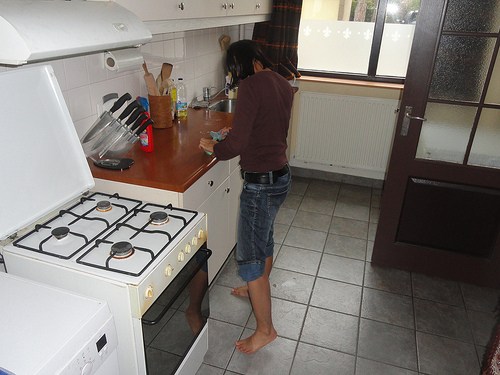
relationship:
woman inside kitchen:
[198, 38, 296, 354] [1, 0, 499, 374]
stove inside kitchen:
[2, 191, 203, 288] [1, 0, 499, 374]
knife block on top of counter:
[76, 109, 139, 166] [85, 87, 234, 192]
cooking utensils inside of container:
[140, 59, 176, 95] [147, 93, 174, 130]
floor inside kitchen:
[192, 174, 499, 374] [1, 0, 499, 374]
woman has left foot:
[198, 38, 296, 354] [234, 327, 278, 356]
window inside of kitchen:
[296, 1, 421, 79] [1, 0, 499, 374]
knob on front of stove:
[143, 281, 154, 300] [2, 191, 203, 288]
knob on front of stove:
[164, 263, 175, 278] [2, 191, 203, 288]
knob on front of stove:
[176, 249, 186, 260] [2, 191, 203, 288]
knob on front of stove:
[183, 241, 191, 255] [2, 191, 203, 288]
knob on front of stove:
[189, 235, 200, 247] [2, 191, 203, 288]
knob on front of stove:
[196, 227, 207, 240] [2, 191, 203, 288]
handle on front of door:
[397, 104, 427, 138] [370, 1, 498, 291]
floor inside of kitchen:
[192, 174, 499, 374] [1, 0, 499, 374]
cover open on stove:
[0, 63, 94, 240] [2, 191, 203, 288]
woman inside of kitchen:
[198, 38, 296, 354] [1, 0, 499, 374]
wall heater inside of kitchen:
[294, 90, 400, 174] [1, 0, 499, 374]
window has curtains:
[296, 1, 421, 79] [249, 0, 305, 94]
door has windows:
[370, 1, 498, 291] [414, 1, 499, 174]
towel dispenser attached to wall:
[103, 48, 144, 71] [0, 20, 241, 142]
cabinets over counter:
[112, 0, 270, 36] [85, 87, 234, 192]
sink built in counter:
[207, 96, 237, 115] [85, 87, 234, 192]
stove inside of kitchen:
[2, 191, 203, 288] [1, 0, 499, 374]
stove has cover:
[2, 191, 203, 288] [0, 63, 94, 240]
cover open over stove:
[0, 63, 94, 240] [2, 191, 203, 288]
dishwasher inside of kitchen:
[48, 314, 123, 374] [1, 0, 499, 374]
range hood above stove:
[0, 0, 152, 69] [2, 191, 203, 288]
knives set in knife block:
[83, 93, 152, 159] [76, 109, 139, 166]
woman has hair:
[198, 38, 296, 354] [224, 37, 275, 86]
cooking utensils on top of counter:
[142, 62, 176, 96] [85, 87, 234, 192]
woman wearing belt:
[198, 38, 296, 354] [237, 163, 288, 183]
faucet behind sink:
[205, 83, 232, 103] [207, 96, 237, 115]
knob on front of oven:
[192, 237, 199, 246] [4, 189, 209, 374]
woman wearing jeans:
[198, 38, 296, 354] [234, 169, 290, 283]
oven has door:
[4, 189, 209, 374] [142, 239, 210, 374]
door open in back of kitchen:
[370, 1, 498, 291] [1, 0, 499, 374]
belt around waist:
[237, 163, 288, 183] [236, 143, 289, 166]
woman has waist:
[198, 38, 296, 354] [236, 143, 289, 166]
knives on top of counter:
[83, 93, 152, 159] [85, 87, 234, 192]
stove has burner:
[2, 191, 203, 288] [118, 202, 194, 239]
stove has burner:
[2, 191, 203, 288] [110, 240, 136, 260]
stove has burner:
[2, 191, 203, 288] [92, 194, 115, 216]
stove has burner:
[2, 191, 203, 288] [17, 210, 107, 256]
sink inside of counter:
[207, 96, 237, 115] [85, 87, 234, 192]